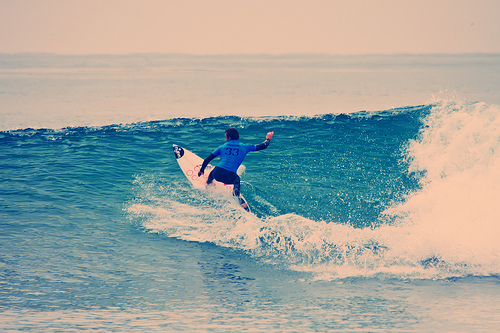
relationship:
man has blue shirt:
[196, 125, 275, 200] [198, 140, 269, 174]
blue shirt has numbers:
[198, 140, 271, 174] [218, 146, 243, 157]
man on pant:
[196, 125, 275, 200] [206, 165, 238, 197]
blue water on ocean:
[0, 100, 430, 304] [1, 52, 497, 330]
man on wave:
[196, 125, 277, 200] [0, 100, 498, 331]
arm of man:
[246, 130, 274, 150] [198, 125, 274, 212]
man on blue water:
[196, 125, 277, 200] [0, 100, 499, 333]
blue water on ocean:
[0, 100, 499, 333] [1, 52, 497, 330]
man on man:
[196, 125, 275, 200] [196, 125, 277, 200]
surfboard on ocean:
[168, 136, 224, 201] [4, 124, 499, 331]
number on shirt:
[223, 146, 241, 159] [206, 140, 257, 174]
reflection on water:
[197, 218, 245, 331] [219, 235, 381, 327]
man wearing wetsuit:
[196, 125, 277, 200] [201, 129, 266, 200]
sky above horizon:
[23, 7, 497, 77] [0, 32, 485, 68]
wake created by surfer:
[135, 160, 443, 291] [205, 119, 272, 207]